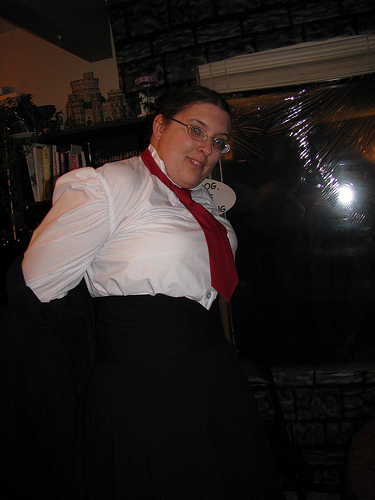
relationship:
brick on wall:
[190, 18, 240, 45] [111, 17, 372, 454]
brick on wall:
[190, 18, 293, 45] [108, 2, 373, 77]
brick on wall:
[190, 18, 293, 45] [0, 2, 373, 111]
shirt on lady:
[75, 120, 229, 270] [21, 74, 274, 499]